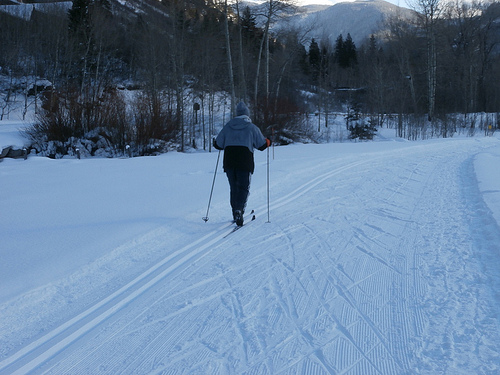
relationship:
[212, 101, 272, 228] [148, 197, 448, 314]
man stands on snow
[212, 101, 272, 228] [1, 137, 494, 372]
man skis on snow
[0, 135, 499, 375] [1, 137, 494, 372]
tracks created in snow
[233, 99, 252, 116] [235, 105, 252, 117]
hat sits on head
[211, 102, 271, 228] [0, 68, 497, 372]
man skiing in snow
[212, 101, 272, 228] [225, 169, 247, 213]
man wearing pant.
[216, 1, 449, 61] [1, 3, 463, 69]
mountain in distance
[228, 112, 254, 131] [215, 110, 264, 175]
hood of jacket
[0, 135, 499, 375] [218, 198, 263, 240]
tracks from skis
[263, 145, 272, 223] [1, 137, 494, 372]
long/thin ski-pole sticking in snow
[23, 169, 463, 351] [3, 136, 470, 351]
snow in ground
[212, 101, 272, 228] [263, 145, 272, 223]
man holding long/thin ski-pole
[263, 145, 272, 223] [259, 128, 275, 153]
long/thin ski-pole in hand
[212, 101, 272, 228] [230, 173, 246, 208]
man wearing pants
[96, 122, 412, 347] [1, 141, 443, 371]
tracks on snow